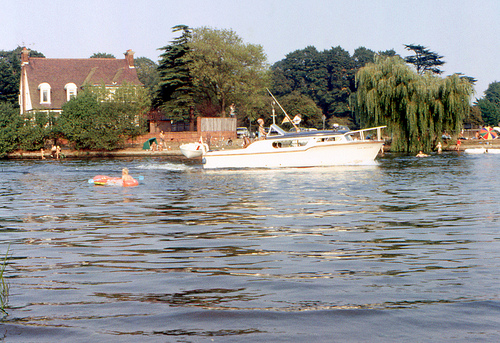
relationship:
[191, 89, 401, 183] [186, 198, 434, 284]
boat moving in water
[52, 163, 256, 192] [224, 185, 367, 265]
people in water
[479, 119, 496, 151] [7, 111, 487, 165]
umbrella at beach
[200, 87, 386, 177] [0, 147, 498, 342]
boat floating on water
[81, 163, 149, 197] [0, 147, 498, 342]
floating person on water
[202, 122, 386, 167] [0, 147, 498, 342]
boat on water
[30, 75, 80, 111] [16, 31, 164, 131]
white windows on houses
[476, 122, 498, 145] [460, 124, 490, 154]
umbrella on shore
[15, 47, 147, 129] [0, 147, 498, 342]
house near water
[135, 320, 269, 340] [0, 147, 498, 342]
ripples in water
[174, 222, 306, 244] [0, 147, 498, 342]
ripples in water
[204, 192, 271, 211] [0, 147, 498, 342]
ripples in water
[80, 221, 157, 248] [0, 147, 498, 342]
ripples in water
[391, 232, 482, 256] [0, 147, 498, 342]
ripples in water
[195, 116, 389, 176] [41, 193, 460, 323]
boat in water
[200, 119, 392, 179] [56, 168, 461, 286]
boat moving in water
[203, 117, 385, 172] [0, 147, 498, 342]
boat moving in water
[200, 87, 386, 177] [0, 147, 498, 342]
boat in water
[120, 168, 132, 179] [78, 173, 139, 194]
man on float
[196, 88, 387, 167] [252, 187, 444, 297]
boat in water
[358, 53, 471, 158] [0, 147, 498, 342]
willow tree along water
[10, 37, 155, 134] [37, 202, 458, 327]
house along water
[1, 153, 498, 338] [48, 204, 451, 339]
waves in water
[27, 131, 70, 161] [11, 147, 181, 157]
people on wall